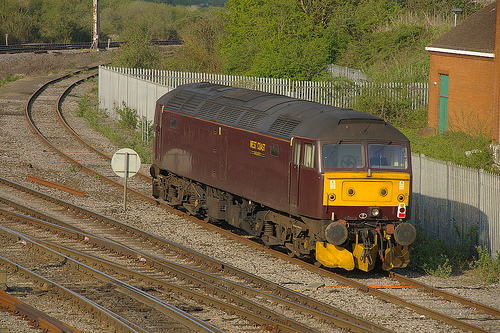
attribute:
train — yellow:
[324, 146, 413, 215]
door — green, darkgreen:
[430, 75, 451, 139]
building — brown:
[419, 17, 494, 144]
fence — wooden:
[250, 71, 421, 101]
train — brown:
[151, 84, 417, 262]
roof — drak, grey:
[454, 18, 497, 42]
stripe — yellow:
[370, 285, 416, 289]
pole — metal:
[26, 170, 91, 201]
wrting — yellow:
[244, 140, 272, 154]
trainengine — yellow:
[330, 173, 418, 213]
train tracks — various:
[23, 94, 79, 260]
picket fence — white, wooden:
[93, 71, 151, 111]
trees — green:
[252, 36, 325, 74]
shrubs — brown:
[168, 17, 222, 70]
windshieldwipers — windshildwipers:
[323, 140, 392, 164]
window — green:
[440, 74, 447, 91]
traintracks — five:
[13, 261, 332, 302]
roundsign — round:
[107, 147, 141, 169]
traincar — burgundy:
[157, 89, 250, 181]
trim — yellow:
[310, 241, 365, 266]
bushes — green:
[215, 38, 328, 66]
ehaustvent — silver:
[174, 91, 195, 111]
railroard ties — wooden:
[180, 293, 198, 309]